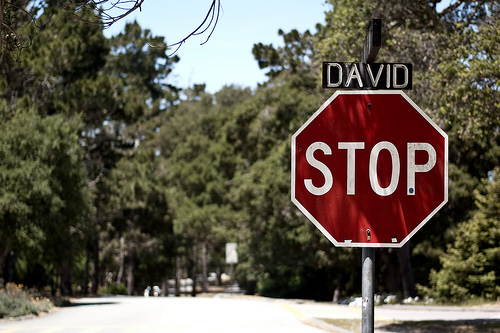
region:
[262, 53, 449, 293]
a red stop sign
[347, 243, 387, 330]
a gray metal pole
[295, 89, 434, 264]
white and red sign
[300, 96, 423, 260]
white letters on sign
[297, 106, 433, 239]
white frame on sign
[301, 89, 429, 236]
red sign is octagonal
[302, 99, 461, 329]
stop sign on grey pole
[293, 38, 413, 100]
black and white road signs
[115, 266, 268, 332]
road is light grey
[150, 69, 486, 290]
thick grove of green trees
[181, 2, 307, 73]
sky is blue and clear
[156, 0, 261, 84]
no clouds in sky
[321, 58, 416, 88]
the name david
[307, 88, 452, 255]
a stop sign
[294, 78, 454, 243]
a red and white stop sign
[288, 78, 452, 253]
a red and white octagon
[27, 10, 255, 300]
several trees in the background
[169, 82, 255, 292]
the trees have green leaves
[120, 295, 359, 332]
an intersection of streets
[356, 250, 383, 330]
a metal pole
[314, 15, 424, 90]
two street signs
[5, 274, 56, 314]
orange flowers on the side of the road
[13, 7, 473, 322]
street lined with trees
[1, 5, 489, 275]
trees lining the streets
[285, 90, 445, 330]
stop sign on a metal pole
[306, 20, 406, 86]
street signs on top of stop sign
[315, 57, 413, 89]
David on top of stop sign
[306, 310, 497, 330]
median to the right of the road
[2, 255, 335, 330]
asphalt road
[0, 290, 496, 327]
asphalt road that forks off to the right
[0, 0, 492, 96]
clear blue sky with no clouds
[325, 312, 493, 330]
dirt and grass in the median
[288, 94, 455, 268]
this is a sign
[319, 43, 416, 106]
this is a sign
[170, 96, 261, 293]
this is a tree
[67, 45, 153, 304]
this is a tree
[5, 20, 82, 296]
this is a tree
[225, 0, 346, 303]
this is a tree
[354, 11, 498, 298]
this is a tree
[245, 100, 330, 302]
this is a tree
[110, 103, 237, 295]
this is a tree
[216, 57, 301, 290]
this is a tree